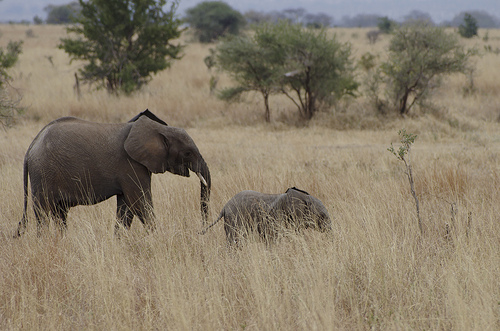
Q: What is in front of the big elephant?
A: Small baby elephant.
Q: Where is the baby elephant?
A: In front of the adult.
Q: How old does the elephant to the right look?
A: Young.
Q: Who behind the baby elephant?
A: Adult.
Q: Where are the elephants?
A: In the wild.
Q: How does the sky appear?
A: Clear and blue.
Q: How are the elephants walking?
A: In a line.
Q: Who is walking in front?
A: Small elephant.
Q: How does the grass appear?
A: Dry and tan.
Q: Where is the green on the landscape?
A: The trees.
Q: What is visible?
A: The elephants.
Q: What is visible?
A: The elephants.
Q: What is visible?
A: The elephants.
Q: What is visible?
A: The elephants.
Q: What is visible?
A: The elephants.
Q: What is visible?
A: The elephants.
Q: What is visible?
A: The elephants.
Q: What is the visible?
A: The elephants.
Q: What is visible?
A: The elephants.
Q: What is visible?
A: The elephants.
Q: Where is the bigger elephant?
A: Behind the smaller one.